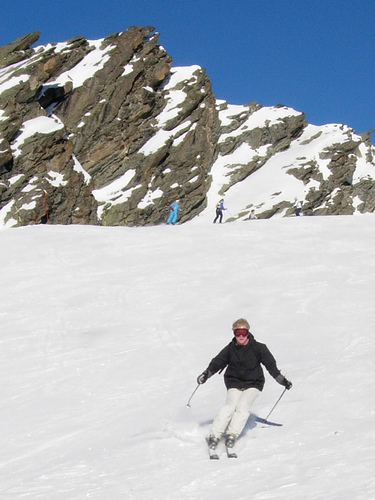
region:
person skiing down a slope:
[151, 307, 306, 473]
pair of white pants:
[199, 383, 264, 441]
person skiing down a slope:
[160, 195, 184, 226]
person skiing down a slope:
[208, 197, 228, 224]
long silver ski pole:
[183, 371, 209, 412]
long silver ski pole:
[259, 381, 287, 427]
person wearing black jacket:
[170, 313, 306, 466]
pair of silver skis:
[203, 429, 241, 463]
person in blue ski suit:
[162, 197, 182, 227]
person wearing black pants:
[205, 196, 231, 224]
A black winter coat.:
[184, 331, 292, 389]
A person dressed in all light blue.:
[166, 192, 182, 231]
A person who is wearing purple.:
[211, 195, 226, 224]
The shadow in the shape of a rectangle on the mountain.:
[26, 75, 69, 109]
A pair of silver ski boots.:
[207, 429, 235, 453]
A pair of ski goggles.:
[231, 325, 249, 337]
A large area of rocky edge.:
[4, 26, 374, 214]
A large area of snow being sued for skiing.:
[5, 213, 373, 498]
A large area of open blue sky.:
[0, 7, 373, 144]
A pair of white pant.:
[209, 377, 260, 445]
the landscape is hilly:
[83, 13, 233, 203]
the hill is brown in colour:
[83, 85, 147, 170]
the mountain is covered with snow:
[47, 18, 172, 139]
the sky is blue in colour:
[207, 10, 327, 89]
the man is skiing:
[154, 289, 277, 458]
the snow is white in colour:
[2, 242, 186, 472]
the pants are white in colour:
[229, 386, 256, 450]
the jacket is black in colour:
[222, 344, 275, 387]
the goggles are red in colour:
[230, 325, 253, 333]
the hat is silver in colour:
[226, 315, 251, 326]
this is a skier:
[111, 368, 329, 452]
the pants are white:
[198, 394, 253, 478]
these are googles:
[225, 316, 255, 344]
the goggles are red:
[208, 310, 256, 379]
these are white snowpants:
[175, 390, 254, 424]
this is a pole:
[189, 375, 207, 396]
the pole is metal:
[167, 386, 203, 402]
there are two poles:
[135, 377, 335, 455]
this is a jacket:
[214, 353, 255, 377]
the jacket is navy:
[216, 355, 235, 391]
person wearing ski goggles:
[182, 317, 294, 461]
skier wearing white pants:
[193, 319, 294, 460]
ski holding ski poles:
[194, 319, 293, 444]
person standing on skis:
[188, 315, 289, 450]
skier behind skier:
[166, 195, 182, 223]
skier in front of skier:
[214, 199, 227, 221]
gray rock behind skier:
[0, 24, 372, 229]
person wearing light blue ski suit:
[166, 196, 182, 222]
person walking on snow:
[165, 198, 185, 224]